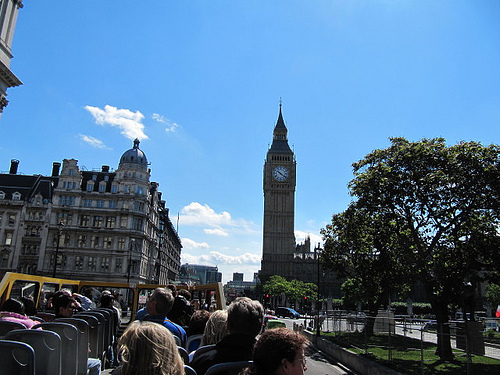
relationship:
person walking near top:
[251, 328, 309, 374] [0, 138, 185, 287]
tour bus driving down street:
[1, 271, 254, 372] [270, 322, 366, 374]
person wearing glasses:
[251, 328, 309, 374] [297, 355, 305, 363]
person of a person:
[251, 328, 309, 374] [251, 328, 309, 374]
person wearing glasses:
[251, 328, 309, 374] [294, 354, 307, 367]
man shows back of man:
[138, 290, 191, 343] [138, 288, 185, 346]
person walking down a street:
[94, 283, 122, 322] [270, 322, 366, 374]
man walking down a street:
[138, 288, 185, 346] [270, 322, 366, 374]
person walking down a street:
[202, 296, 285, 365] [270, 322, 366, 374]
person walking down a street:
[96, 330, 172, 375] [270, 322, 366, 374]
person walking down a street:
[244, 317, 311, 374] [270, 322, 366, 374]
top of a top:
[0, 138, 200, 242] [0, 138, 185, 287]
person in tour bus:
[194, 298, 266, 373] [1, 271, 254, 372]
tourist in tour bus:
[45, 286, 84, 317] [1, 271, 254, 372]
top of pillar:
[270, 95, 290, 140] [261, 148, 296, 275]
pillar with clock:
[237, 96, 322, 281] [260, 154, 314, 184]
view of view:
[0, 1, 499, 284] [0, 1, 499, 284]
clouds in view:
[88, 97, 137, 132] [0, 1, 499, 284]